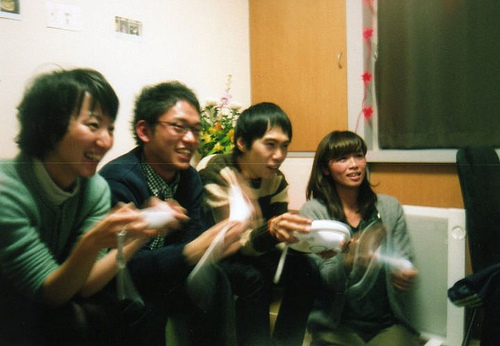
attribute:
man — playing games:
[200, 98, 321, 344]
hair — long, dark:
[306, 124, 382, 227]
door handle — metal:
[331, 45, 349, 75]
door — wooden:
[249, 0, 353, 160]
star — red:
[358, 103, 382, 126]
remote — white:
[121, 204, 189, 241]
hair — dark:
[234, 102, 296, 144]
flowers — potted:
[195, 75, 253, 169]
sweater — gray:
[297, 187, 421, 336]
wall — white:
[5, 0, 253, 187]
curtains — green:
[366, 8, 499, 154]